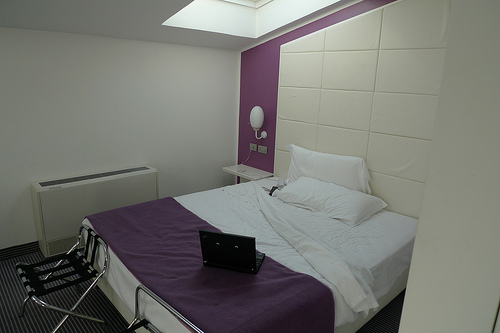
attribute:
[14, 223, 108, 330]
chair — metal, fancy, small, black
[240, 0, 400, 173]
wall — purple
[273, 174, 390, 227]
pillow — white, fluffy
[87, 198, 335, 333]
blanket — purple, thin, long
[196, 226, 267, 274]
computer — laptop, expensive looking, small, black, opened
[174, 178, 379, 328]
blanket — linen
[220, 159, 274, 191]
table — small, white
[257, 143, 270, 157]
electrical plate — silver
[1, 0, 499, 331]
bedroom — modern, plush, single person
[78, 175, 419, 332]
bed — plush, purple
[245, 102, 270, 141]
lamp — modernistic, small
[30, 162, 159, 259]
heater — small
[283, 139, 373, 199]
pillow — white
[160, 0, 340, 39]
skylight window — large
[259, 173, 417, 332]
sheet — white